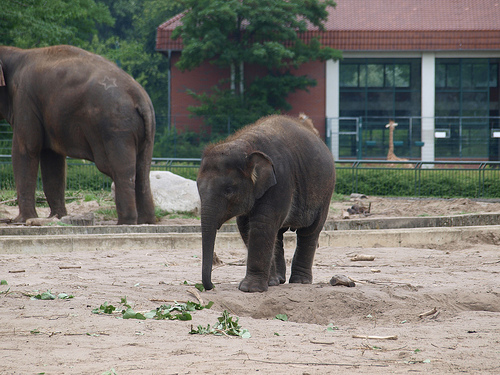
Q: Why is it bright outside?
A: It's daytime.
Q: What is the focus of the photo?
A: Elephants.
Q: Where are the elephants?
A: Zoo.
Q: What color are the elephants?
A: Brown.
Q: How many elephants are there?
A: Two.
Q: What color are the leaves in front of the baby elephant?
A: Green.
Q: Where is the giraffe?
A: Background.